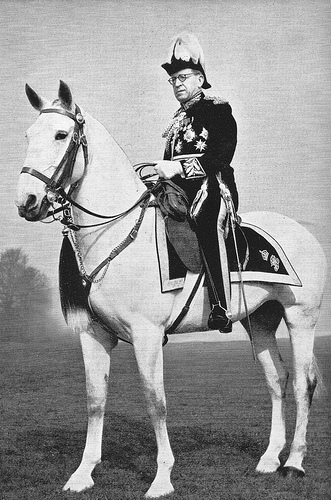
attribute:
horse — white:
[13, 79, 328, 498]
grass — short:
[3, 339, 329, 499]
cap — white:
[160, 32, 213, 85]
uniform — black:
[169, 97, 240, 312]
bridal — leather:
[24, 107, 85, 199]